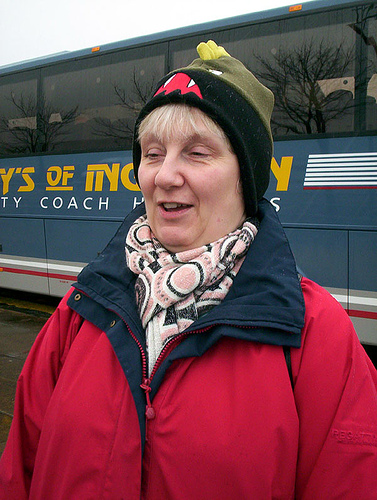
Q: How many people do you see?
A: One.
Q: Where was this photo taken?
A: Outside by a bus.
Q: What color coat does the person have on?
A: Red.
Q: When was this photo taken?
A: During the day.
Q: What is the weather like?
A: Cold.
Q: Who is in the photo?
A: A woman.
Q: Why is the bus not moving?
A: It is parked.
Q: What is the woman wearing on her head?
A: A hat.